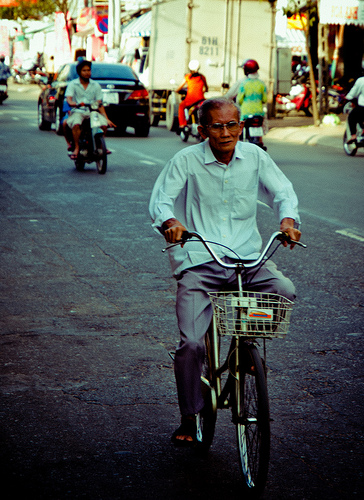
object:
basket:
[207, 284, 294, 339]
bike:
[162, 223, 305, 491]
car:
[39, 59, 150, 136]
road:
[6, 86, 362, 486]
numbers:
[199, 45, 205, 57]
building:
[68, 1, 110, 57]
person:
[227, 58, 270, 149]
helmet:
[244, 58, 259, 73]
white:
[103, 89, 118, 98]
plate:
[96, 89, 119, 106]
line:
[106, 133, 363, 258]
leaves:
[34, 3, 41, 16]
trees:
[2, 1, 54, 15]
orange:
[177, 78, 207, 121]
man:
[146, 95, 302, 448]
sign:
[249, 305, 274, 319]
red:
[246, 59, 260, 75]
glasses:
[212, 118, 238, 131]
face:
[210, 111, 239, 146]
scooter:
[64, 112, 113, 173]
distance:
[1, 1, 364, 125]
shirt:
[148, 144, 305, 268]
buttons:
[224, 180, 227, 184]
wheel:
[229, 345, 274, 491]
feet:
[170, 423, 194, 447]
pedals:
[173, 429, 195, 450]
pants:
[161, 257, 298, 418]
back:
[77, 65, 150, 137]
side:
[118, 1, 193, 92]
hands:
[161, 218, 190, 243]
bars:
[160, 222, 307, 270]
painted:
[137, 152, 164, 169]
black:
[37, 191, 136, 337]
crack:
[95, 235, 125, 274]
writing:
[196, 33, 224, 58]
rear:
[191, 0, 278, 111]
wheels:
[94, 139, 111, 174]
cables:
[176, 237, 248, 289]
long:
[147, 148, 190, 229]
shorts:
[65, 106, 89, 127]